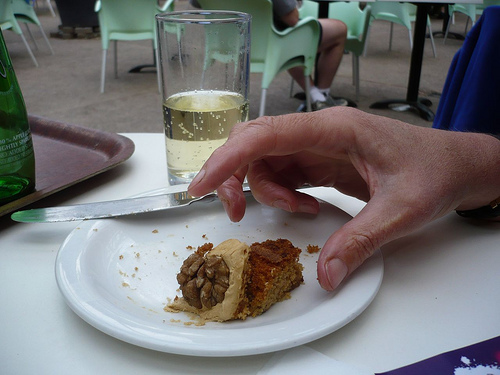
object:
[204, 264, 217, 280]
nuts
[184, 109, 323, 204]
finger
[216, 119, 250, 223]
finger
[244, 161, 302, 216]
finger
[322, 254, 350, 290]
nail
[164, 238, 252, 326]
gravy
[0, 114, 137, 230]
tray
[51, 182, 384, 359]
plate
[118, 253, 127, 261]
crubs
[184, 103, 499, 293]
hand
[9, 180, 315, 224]
knife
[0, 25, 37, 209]
bottle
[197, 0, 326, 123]
chair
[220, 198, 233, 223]
nail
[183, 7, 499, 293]
person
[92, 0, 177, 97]
green chair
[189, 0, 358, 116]
person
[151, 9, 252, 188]
glass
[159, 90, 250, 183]
liquid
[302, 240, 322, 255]
crumbs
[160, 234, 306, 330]
food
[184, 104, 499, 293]
person